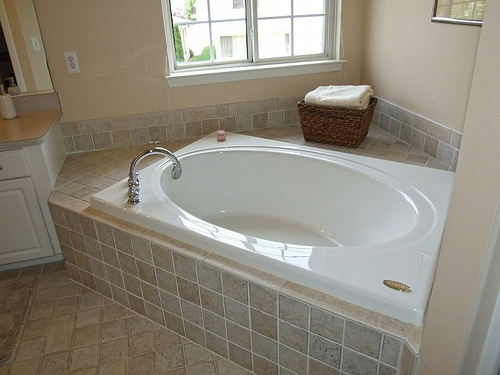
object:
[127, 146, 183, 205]
faucet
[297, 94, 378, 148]
basket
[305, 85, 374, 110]
towel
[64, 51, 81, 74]
electrical socket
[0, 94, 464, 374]
tile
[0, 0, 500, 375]
bathroom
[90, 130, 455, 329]
bathtub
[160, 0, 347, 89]
window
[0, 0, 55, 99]
mirror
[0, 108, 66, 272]
dresser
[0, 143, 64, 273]
compartment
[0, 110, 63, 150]
counter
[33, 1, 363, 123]
wall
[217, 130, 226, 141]
bottle